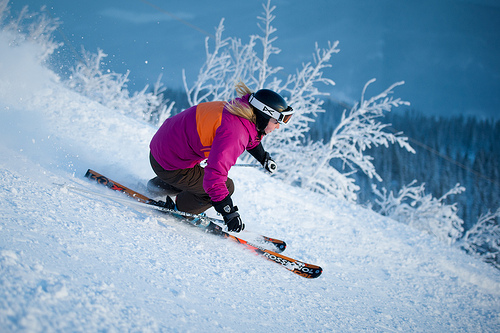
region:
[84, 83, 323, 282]
A woman skiing.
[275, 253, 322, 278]
Part of a colorful ski.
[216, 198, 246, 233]
The woman's black glove.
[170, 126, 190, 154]
Part of the woman's jacket.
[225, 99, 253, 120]
Part of the woman's hair.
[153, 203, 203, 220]
Part of a ski pole.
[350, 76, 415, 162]
Part of a snow covered tree.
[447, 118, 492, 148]
Trees in the distance.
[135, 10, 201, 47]
Part of the blue sky.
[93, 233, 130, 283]
Part of the snow.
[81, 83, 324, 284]
woman crouching on skies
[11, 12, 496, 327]
snowy mountain landscape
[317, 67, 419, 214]
snow covered tree limb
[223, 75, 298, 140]
woman with blonde hair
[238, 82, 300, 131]
woman with white goggles on her head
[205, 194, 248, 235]
black glove on right arm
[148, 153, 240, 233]
brown colored pants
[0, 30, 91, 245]
snow covered ground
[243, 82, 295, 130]
black helmet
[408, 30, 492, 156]
blue colored sky above tree line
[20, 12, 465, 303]
young woman skiing downhill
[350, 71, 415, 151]
branches encased in ice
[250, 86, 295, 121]
black helmet with goggles up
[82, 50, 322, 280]
skier crouched low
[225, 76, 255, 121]
wind blown blond hair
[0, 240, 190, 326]
close-up of the white slope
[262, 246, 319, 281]
brand name on the ski's tip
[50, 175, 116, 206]
white ski pole touches the ground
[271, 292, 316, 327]
patch of white snow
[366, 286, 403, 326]
patch of white snow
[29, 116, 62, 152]
patch of white snow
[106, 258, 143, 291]
patch of white snow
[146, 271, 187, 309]
patch of white snow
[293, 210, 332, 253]
patch of white snow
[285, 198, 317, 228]
patch of white snow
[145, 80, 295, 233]
woman is skiing down the mountain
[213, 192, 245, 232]
gloves is on womans hand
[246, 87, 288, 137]
helmet is on ladies head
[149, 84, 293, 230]
lady is on skis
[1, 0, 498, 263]
branches are covered in snow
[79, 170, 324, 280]
skis are in the snow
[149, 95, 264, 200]
jacket is pink